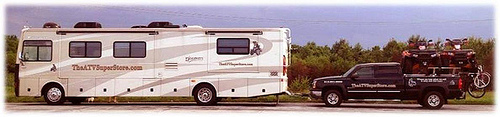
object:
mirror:
[14, 49, 24, 59]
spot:
[146, 81, 160, 84]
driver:
[32, 48, 50, 61]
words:
[183, 56, 204, 63]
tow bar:
[284, 91, 294, 97]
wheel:
[471, 72, 494, 88]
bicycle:
[461, 63, 493, 98]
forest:
[296, 49, 347, 77]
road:
[0, 101, 499, 117]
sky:
[7, 5, 490, 51]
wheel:
[193, 82, 218, 105]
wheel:
[42, 83, 67, 105]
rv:
[14, 22, 294, 104]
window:
[112, 42, 144, 58]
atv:
[400, 40, 443, 74]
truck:
[309, 61, 467, 110]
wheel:
[323, 90, 342, 107]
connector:
[306, 96, 314, 101]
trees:
[364, 44, 391, 61]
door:
[345, 66, 376, 97]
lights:
[312, 80, 319, 89]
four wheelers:
[436, 38, 477, 75]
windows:
[69, 41, 103, 58]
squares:
[68, 78, 96, 97]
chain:
[293, 95, 308, 99]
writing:
[347, 83, 397, 89]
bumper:
[52, 30, 157, 35]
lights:
[40, 22, 59, 28]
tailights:
[457, 78, 465, 89]